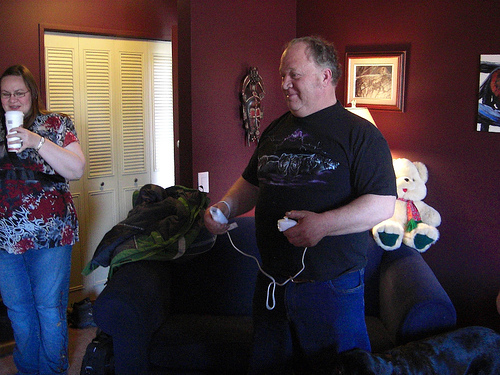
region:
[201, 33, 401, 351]
man holding a Wii controls in both hands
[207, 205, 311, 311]
two wii remotes connected by a white cord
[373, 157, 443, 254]
white stuffed bear wearing a scarf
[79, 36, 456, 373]
man standing in front of a couch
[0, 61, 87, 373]
standing woman holding a white cup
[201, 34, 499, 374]
black dog next to a man playing wii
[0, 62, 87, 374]
woman wearing a floral top and jeans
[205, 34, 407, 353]
man in a black shirt playing a game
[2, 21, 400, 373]
man and woman standing in a room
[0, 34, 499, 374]
woman man and dog in a room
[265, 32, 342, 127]
head of a person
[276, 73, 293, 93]
nose of a person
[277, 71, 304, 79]
eye of a person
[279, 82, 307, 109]
mouth of a person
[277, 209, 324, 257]
hand of a person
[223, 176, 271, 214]
arm of a person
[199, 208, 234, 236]
hand of a person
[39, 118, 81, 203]
arm of a person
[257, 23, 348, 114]
head of a person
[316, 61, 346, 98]
ear of a person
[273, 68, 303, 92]
nose of a person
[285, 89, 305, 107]
mouth of a person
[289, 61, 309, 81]
eye of a person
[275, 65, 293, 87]
eye of a person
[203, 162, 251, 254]
arm of a person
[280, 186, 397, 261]
arm of a person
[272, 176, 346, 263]
hand of a person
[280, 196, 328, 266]
fingers of a person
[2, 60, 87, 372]
The woman is holding a cup.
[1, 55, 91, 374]
The woman is wearing glasses.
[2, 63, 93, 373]
The woman is standing.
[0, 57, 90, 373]
The woman is smiling.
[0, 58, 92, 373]
The woman is wearing blue jeans.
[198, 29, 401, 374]
The man is holding game controllers.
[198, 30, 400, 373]
The man is wearing blue jeans.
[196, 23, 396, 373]
The man is smiling.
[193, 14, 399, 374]
The man is wearing a black shirt.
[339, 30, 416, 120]
The picture is framed.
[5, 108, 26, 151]
white disposable coffee cup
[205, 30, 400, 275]
man in black shirt playing the Wii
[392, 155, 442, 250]
white stuffed bear with red scarf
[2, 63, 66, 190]
woman drinking cup of coffee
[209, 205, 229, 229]
white Wii remote control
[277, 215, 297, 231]
White gaming nunchuk for Wii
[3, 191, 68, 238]
white, black and white patterned shirt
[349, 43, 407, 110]
framed picture hanging on wall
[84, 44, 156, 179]
white bi-fold closet doors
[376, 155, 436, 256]
the teddy bear on the couch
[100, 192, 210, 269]
the coats on the couch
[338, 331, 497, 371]
dog standing by the man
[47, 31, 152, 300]
the white closet doors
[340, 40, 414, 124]
the picture on the wall with the wooden frame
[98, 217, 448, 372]
the couch by the man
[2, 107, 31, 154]
coffee cup in her hand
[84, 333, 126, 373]
black bag on the floor by the couch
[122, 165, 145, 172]
white wooden slat on door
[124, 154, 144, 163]
white wooden slat on door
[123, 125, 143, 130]
white wooden slat on door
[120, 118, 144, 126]
white wooden slat on door